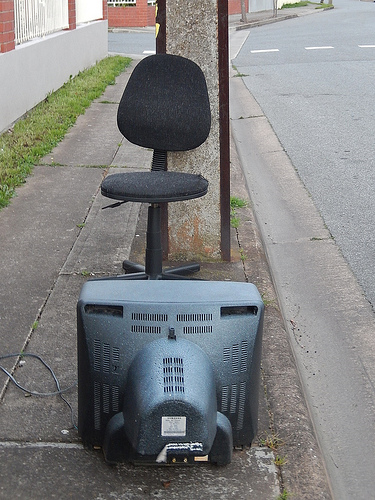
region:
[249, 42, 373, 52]
white lines on asphalt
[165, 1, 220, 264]
bark on tree trunk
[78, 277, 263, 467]
back of black television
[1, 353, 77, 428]
electrical cord on cement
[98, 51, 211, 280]
computer chair with plastic base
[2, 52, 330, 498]
cement suface of sidewalk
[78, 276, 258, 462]
an abandoned tv on the sidewalk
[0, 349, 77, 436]
wires trailing from tv set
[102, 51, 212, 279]
high low spinning office chair with wheels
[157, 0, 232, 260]
cement wall running along sidewalk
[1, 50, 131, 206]
grassy area between fence and sidewalk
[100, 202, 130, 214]
lever to raise and lower seat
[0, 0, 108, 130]
cement, brick, and metal fence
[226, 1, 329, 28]
sidewalk across the street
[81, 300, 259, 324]
holes that serve as handles for the tv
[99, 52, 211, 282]
An armless desk chair sitting on a sidewalk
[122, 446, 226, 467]
Audio and video connections on the back of a television set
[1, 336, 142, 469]
Wires connected to a television set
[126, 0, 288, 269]
A cement pillar in the center of a sidewalk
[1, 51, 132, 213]
A patch of grass growing next to a sidewalk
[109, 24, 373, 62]
White lines on the road to guide traffic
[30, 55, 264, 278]
A sidewalk with grass growing in the cracks of cement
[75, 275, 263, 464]
A TV on the side of the road.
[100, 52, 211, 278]
A chair on the side of the road.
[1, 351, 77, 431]
A cord that connects to the TV.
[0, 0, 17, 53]
Red brick on the side of the building.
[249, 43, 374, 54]
White lines crossing the road.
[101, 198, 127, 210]
Handle on the chair to raise and lower the seat.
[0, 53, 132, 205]
A patch of grass between the building and the sidewalk.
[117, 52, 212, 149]
The back of the chair.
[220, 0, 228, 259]
A rusted strip of metal.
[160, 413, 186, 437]
A white tag on the back of the TV.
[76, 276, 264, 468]
Plastic back of television set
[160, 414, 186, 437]
Manufacturer label on back of television set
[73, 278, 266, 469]
Abandoned television set on sidewalk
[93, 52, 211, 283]
Black desk chair on sidewalk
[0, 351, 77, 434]
Power cord of television set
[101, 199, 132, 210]
Metal chair adjustment handle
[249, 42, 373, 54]
Pedestrian crossing area painted on street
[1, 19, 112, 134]
Concrete wall fence base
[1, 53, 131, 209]
grass median along sidewalk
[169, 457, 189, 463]
Auxiliary cable jacks on back of television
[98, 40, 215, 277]
a black chair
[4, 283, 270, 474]
a tv set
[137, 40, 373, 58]
white lines on street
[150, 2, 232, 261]
a brick post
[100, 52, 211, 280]
A black armless office chair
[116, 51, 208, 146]
back cushion of an office chair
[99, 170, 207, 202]
seat cushion of an office chair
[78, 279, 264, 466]
back of an old CRT television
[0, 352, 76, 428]
a black electrical cord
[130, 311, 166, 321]
vent holes on an old TV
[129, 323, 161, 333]
vent holes on an old TV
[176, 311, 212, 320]
vent holes on an old TV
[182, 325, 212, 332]
vent holes on an old TV